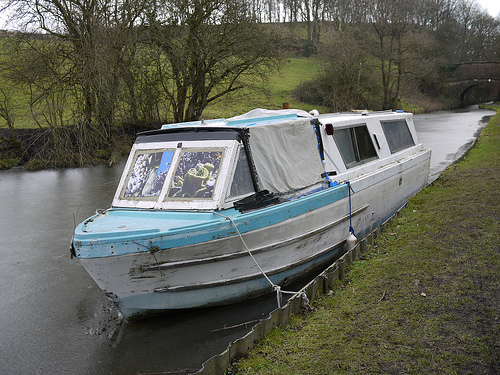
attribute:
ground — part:
[390, 183, 500, 374]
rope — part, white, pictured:
[210, 207, 309, 308]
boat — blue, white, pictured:
[57, 91, 445, 321]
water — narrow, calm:
[2, 86, 488, 372]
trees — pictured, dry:
[11, 2, 267, 113]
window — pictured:
[104, 136, 240, 213]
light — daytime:
[5, 4, 499, 371]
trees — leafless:
[213, 0, 499, 34]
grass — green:
[345, 174, 500, 370]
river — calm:
[0, 167, 76, 373]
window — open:
[327, 124, 380, 168]